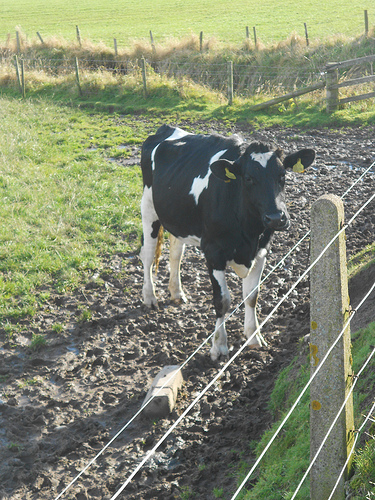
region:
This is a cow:
[99, 105, 305, 360]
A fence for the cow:
[84, 245, 339, 474]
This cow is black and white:
[91, 109, 318, 447]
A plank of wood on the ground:
[106, 336, 214, 423]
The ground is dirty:
[35, 360, 165, 481]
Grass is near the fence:
[240, 311, 366, 496]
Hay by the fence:
[25, 13, 220, 111]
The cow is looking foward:
[180, 114, 328, 238]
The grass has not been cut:
[4, 90, 135, 228]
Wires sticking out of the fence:
[310, 205, 372, 461]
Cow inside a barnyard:
[123, 113, 321, 362]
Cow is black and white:
[118, 111, 317, 364]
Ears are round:
[207, 142, 319, 188]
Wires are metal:
[115, 217, 371, 493]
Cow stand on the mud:
[110, 118, 323, 445]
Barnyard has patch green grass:
[0, 97, 139, 328]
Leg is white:
[237, 269, 273, 367]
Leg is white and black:
[200, 262, 236, 365]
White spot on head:
[246, 142, 279, 174]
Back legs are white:
[125, 239, 193, 315]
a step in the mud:
[99, 387, 114, 408]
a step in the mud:
[164, 444, 177, 461]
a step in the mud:
[174, 433, 187, 457]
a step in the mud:
[91, 477, 102, 493]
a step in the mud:
[39, 458, 57, 477]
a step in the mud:
[29, 416, 40, 427]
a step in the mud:
[50, 389, 60, 401]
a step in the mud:
[203, 392, 213, 404]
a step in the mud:
[159, 345, 170, 355]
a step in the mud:
[28, 471, 45, 493]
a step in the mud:
[56, 443, 79, 463]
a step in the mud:
[80, 396, 89, 405]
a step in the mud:
[180, 439, 189, 452]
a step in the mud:
[145, 471, 160, 487]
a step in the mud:
[33, 444, 43, 455]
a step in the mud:
[64, 382, 72, 391]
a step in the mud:
[131, 352, 136, 357]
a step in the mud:
[61, 356, 69, 366]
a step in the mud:
[129, 305, 138, 314]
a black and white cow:
[95, 126, 340, 327]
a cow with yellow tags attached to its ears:
[190, 137, 320, 238]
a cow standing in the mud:
[106, 116, 316, 493]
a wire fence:
[12, 58, 353, 98]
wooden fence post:
[9, 52, 249, 97]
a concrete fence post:
[258, 182, 352, 490]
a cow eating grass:
[196, 136, 322, 253]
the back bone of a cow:
[115, 123, 326, 221]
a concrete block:
[132, 349, 201, 423]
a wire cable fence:
[144, 230, 312, 436]